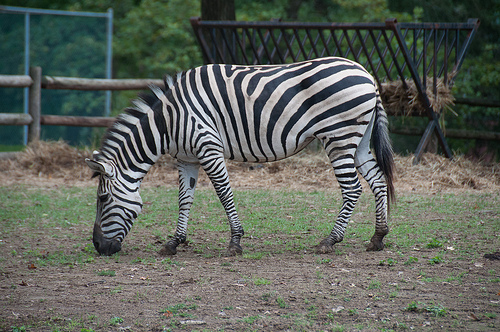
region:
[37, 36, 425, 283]
Medium sized black and white zebra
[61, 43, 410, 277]
Zebra eating some grass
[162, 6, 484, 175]
Black metal hay dispenser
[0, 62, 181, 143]
Fence made of wooden poles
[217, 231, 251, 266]
Dirty grey zebra hoof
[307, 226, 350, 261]
Dirty grey zebra hoof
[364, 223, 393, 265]
Dirty grey zebra hoof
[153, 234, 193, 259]
Dirty grey zebra hoof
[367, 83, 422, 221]
Black and white zebra tail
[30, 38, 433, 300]
Black and white zebra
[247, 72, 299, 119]
black and white stripes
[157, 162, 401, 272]
four zebra legs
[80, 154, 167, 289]
zebra grazing on grass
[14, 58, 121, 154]
wooden barrier fence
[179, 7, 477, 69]
black metal feeding trough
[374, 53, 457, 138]
brown hay in feeding trough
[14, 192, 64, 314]
green scrubby patchy grass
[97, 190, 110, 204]
black eye on a zebra's head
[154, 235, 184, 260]
dirty zebra hoof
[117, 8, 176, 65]
green bushes in the background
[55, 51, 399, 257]
zebra eating grass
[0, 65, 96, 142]
wooden fence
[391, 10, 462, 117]
black metal hopper with some hay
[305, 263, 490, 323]
field of grass with dry patches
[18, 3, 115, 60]
chain link fencing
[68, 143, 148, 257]
zebra eating grass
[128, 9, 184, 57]
green foliage in background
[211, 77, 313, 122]
black and white stripes on zebra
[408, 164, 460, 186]
loose hay on ground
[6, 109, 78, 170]
hay against wooden fence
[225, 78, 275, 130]
black and white stripes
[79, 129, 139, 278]
a zebra head bent down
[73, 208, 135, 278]
a zebra grazing on grass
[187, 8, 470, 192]
a feeding trough with hay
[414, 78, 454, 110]
hay to feed the zebra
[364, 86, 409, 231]
tail on a zebra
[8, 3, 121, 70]
chain link fence behind a wooden fence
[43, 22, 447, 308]
a zebra in a zoo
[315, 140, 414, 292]
hind legs on a zebra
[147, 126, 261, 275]
front legs on a zebra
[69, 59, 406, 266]
a zebra eating grass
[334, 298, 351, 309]
a dead leaf on the ground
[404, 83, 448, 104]
hay in a trough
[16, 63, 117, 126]
a wooden fence enclosing the area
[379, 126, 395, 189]
spiky hair on a tail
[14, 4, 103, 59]
a mesh partition next to the fence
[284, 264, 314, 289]
gray dirt on the ground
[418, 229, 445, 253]
a clump of grass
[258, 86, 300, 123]
black stripes on a zebra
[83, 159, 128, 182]
ears on a head